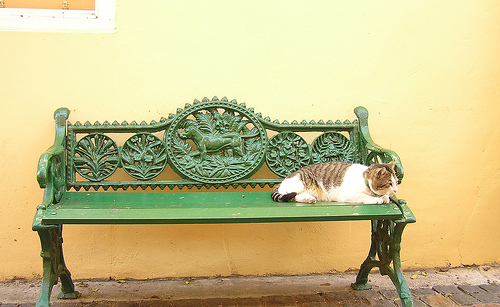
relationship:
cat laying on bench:
[270, 160, 397, 205] [31, 103, 421, 304]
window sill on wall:
[1, 8, 111, 28] [0, 2, 500, 275]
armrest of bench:
[32, 103, 64, 204] [31, 103, 421, 304]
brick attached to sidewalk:
[441, 279, 485, 306] [13, 270, 498, 305]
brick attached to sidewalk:
[410, 277, 440, 300] [13, 270, 498, 305]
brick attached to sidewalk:
[450, 293, 488, 305] [27, 251, 498, 301]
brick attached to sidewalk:
[360, 284, 399, 305] [28, 268, 497, 306]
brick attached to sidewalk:
[366, 298, 396, 307] [13, 270, 498, 305]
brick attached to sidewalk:
[287, 282, 337, 305] [28, 260, 498, 300]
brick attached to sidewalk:
[256, 281, 299, 305] [17, 266, 491, 300]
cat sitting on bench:
[270, 160, 397, 205] [31, 103, 421, 304]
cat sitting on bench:
[270, 160, 397, 205] [70, 116, 416, 286]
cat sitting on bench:
[270, 159, 390, 210] [31, 103, 421, 304]